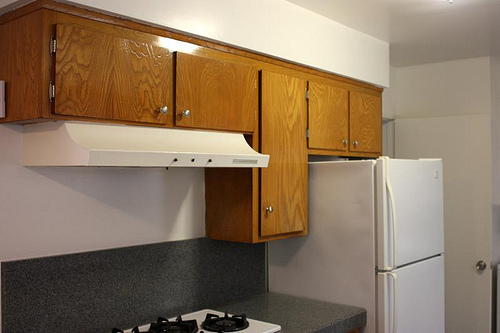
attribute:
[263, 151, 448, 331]
refrigerator — white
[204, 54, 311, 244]
cabinet — wood, wooden, veneer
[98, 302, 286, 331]
stovetop — gas, off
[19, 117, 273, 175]
air vent — white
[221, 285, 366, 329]
countertop — grey, empty, gray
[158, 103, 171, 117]
knob — silver, metallic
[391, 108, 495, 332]
door — white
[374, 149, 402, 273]
handle — white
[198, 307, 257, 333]
burner — black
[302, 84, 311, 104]
hinge — metallic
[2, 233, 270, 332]
trim — gray